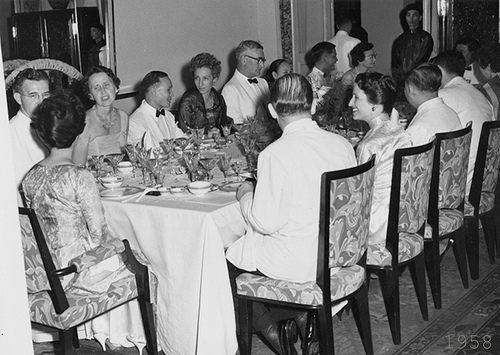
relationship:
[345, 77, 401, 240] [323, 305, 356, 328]
woman wearing stilettos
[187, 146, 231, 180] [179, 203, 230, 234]
glass on top of table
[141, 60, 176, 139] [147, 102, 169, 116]
man wearing bow tie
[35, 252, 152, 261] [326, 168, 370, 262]
armest attached to chair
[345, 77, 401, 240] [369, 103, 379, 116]
woman wearing earring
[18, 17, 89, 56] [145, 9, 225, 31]
mirror on wall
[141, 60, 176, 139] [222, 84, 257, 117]
man wearing suit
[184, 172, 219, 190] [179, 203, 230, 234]
plate on table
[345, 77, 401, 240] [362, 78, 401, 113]
woman has hair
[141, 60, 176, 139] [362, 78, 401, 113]
man has hair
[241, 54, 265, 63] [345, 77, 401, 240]
glasses on woman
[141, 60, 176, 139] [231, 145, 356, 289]
man wearing jacket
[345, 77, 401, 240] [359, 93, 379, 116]
woman wearing earrings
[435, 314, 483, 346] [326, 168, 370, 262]
rug behind chair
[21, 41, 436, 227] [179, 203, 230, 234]
people at table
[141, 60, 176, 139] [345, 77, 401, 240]
man and woman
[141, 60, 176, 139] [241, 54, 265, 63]
man wearing glasses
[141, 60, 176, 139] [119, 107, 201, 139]
man wearing shirt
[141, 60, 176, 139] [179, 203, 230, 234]
man near table